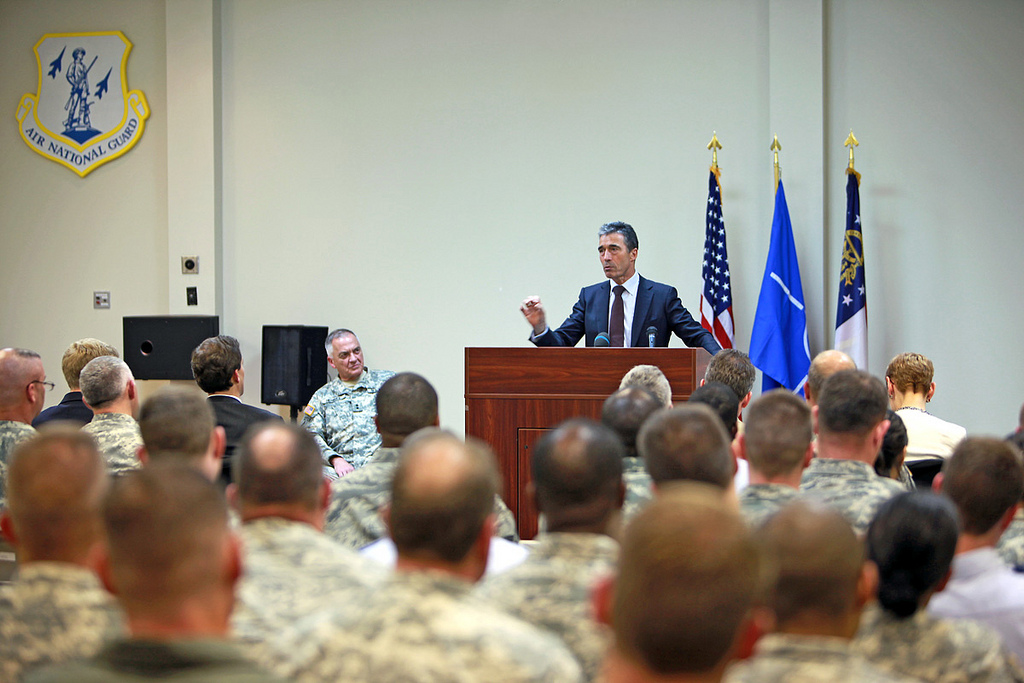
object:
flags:
[699, 165, 868, 402]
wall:
[164, 0, 826, 443]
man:
[518, 221, 720, 354]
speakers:
[121, 316, 327, 405]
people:
[16, 462, 281, 683]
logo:
[14, 29, 149, 179]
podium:
[465, 347, 714, 540]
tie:
[610, 286, 626, 348]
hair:
[866, 493, 961, 619]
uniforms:
[0, 560, 131, 683]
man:
[276, 436, 583, 683]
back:
[2, 526, 1023, 679]